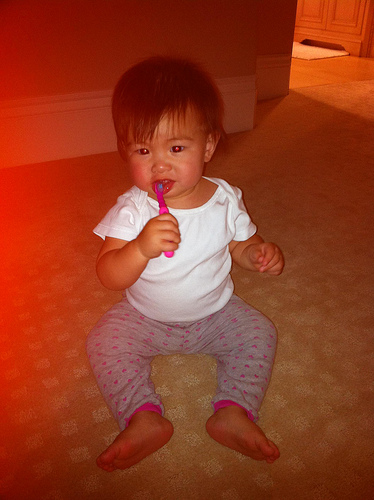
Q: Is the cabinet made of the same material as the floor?
A: Yes, both the cabinet and the floor are made of wood.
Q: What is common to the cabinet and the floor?
A: The material, both the cabinet and the floor are wooden.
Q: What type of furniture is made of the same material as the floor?
A: The cabinet is made of the same material as the floor.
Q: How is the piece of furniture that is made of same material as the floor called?
A: The piece of furniture is a cabinet.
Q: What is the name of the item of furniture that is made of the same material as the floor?
A: The piece of furniture is a cabinet.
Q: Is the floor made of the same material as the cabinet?
A: Yes, both the floor and the cabinet are made of wood.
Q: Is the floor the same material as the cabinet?
A: Yes, both the floor and the cabinet are made of wood.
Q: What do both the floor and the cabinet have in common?
A: The material, both the floor and the cabinet are wooden.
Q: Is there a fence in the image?
A: No, there are no fences.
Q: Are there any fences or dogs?
A: No, there are no fences or dogs.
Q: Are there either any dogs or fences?
A: No, there are no fences or dogs.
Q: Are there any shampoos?
A: No, there are no shampoos.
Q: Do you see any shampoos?
A: No, there are no shampoos.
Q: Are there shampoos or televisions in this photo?
A: No, there are no shampoos or televisions.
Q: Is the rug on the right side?
A: Yes, the rug is on the right of the image.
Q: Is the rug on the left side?
A: No, the rug is on the right of the image.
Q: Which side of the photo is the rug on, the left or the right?
A: The rug is on the right of the image.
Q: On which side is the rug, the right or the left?
A: The rug is on the right of the image.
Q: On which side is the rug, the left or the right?
A: The rug is on the right of the image.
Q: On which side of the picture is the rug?
A: The rug is on the right of the image.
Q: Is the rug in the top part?
A: Yes, the rug is in the top of the image.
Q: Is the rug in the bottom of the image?
A: No, the rug is in the top of the image.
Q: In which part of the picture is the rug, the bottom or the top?
A: The rug is in the top of the image.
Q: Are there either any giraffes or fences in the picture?
A: No, there are no fences or giraffes.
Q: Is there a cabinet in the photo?
A: Yes, there is a cabinet.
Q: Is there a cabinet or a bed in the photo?
A: Yes, there is a cabinet.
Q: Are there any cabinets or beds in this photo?
A: Yes, there is a cabinet.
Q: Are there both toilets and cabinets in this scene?
A: No, there is a cabinet but no toilets.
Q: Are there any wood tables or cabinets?
A: Yes, there is a wood cabinet.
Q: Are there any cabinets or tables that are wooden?
A: Yes, the cabinet is wooden.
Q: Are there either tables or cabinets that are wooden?
A: Yes, the cabinet is wooden.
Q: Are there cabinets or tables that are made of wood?
A: Yes, the cabinet is made of wood.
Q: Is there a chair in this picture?
A: No, there are no chairs.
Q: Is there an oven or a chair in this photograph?
A: No, there are no chairs or ovens.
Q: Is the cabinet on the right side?
A: Yes, the cabinet is on the right of the image.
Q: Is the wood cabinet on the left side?
A: No, the cabinet is on the right of the image.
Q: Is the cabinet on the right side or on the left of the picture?
A: The cabinet is on the right of the image.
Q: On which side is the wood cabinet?
A: The cabinet is on the right of the image.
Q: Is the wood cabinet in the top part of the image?
A: Yes, the cabinet is in the top of the image.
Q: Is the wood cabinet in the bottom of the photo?
A: No, the cabinet is in the top of the image.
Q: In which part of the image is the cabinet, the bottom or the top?
A: The cabinet is in the top of the image.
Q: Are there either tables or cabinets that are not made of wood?
A: No, there is a cabinet but it is made of wood.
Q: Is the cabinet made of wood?
A: Yes, the cabinet is made of wood.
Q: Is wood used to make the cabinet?
A: Yes, the cabinet is made of wood.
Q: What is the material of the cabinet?
A: The cabinet is made of wood.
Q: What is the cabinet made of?
A: The cabinet is made of wood.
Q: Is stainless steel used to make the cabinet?
A: No, the cabinet is made of wood.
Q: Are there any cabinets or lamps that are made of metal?
A: No, there is a cabinet but it is made of wood.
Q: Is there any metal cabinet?
A: No, there is a cabinet but it is made of wood.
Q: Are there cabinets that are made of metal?
A: No, there is a cabinet but it is made of wood.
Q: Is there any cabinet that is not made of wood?
A: No, there is a cabinet but it is made of wood.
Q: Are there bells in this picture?
A: No, there are no bells.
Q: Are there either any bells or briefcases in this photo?
A: No, there are no bells or briefcases.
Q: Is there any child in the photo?
A: Yes, there is a child.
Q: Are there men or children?
A: Yes, there is a child.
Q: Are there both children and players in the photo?
A: No, there is a child but no players.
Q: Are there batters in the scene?
A: No, there are no batters.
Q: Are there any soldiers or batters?
A: No, there are no batters or soldiers.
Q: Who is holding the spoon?
A: The child is holding the spoon.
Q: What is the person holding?
A: The child is holding the spoon.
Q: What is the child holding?
A: The child is holding the spoon.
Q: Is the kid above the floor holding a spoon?
A: Yes, the child is holding a spoon.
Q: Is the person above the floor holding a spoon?
A: Yes, the child is holding a spoon.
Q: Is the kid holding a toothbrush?
A: No, the kid is holding a spoon.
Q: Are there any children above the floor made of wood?
A: Yes, there is a child above the floor.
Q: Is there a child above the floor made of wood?
A: Yes, there is a child above the floor.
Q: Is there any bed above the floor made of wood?
A: No, there is a child above the floor.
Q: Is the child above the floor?
A: Yes, the child is above the floor.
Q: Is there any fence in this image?
A: No, there are no fences.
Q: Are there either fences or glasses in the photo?
A: No, there are no fences or glasses.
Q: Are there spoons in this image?
A: Yes, there is a spoon.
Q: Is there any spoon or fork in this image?
A: Yes, there is a spoon.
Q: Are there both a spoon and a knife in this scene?
A: No, there is a spoon but no knives.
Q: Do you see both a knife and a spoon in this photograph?
A: No, there is a spoon but no knives.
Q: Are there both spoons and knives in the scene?
A: No, there is a spoon but no knives.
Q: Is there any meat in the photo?
A: No, there is no meat.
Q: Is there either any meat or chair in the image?
A: No, there are no meat or chairs.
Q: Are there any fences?
A: No, there are no fences.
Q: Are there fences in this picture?
A: No, there are no fences.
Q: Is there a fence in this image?
A: No, there are no fences.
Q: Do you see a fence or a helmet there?
A: No, there are no fences or helmets.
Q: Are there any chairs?
A: No, there are no chairs.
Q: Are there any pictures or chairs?
A: No, there are no chairs or pictures.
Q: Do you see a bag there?
A: No, there are no bags.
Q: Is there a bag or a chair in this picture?
A: No, there are no bags or chairs.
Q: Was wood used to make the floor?
A: Yes, the floor is made of wood.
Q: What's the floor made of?
A: The floor is made of wood.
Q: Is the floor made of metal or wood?
A: The floor is made of wood.